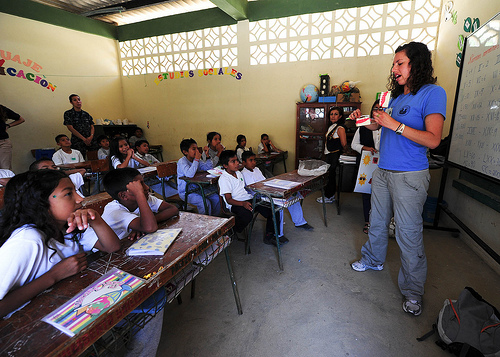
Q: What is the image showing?
A: It is showing a classroom.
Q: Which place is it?
A: It is a classroom.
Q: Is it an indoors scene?
A: Yes, it is indoors.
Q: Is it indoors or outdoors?
A: It is indoors.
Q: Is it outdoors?
A: No, it is indoors.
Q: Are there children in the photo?
A: Yes, there is a child.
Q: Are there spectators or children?
A: Yes, there is a child.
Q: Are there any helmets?
A: No, there are no helmets.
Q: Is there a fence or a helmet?
A: No, there are no helmets or fences.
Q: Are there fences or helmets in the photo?
A: No, there are no helmets or fences.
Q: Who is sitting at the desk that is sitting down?
A: The child is sitting at the desk.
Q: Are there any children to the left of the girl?
A: Yes, there is a child to the left of the girl.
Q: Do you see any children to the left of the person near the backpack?
A: Yes, there is a child to the left of the girl.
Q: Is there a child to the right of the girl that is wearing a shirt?
A: No, the child is to the left of the girl.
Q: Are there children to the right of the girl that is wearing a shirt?
A: No, the child is to the left of the girl.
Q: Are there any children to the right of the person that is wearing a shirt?
A: No, the child is to the left of the girl.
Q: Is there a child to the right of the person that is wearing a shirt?
A: No, the child is to the left of the girl.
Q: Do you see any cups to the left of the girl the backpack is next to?
A: No, there is a child to the left of the girl.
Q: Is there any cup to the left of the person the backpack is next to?
A: No, there is a child to the left of the girl.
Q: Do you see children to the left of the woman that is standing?
A: Yes, there is a child to the left of the woman.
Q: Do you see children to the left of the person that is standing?
A: Yes, there is a child to the left of the woman.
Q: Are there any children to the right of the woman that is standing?
A: No, the child is to the left of the woman.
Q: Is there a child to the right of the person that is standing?
A: No, the child is to the left of the woman.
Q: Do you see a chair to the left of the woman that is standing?
A: No, there is a child to the left of the woman.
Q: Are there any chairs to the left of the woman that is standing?
A: No, there is a child to the left of the woman.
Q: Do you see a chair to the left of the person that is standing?
A: No, there is a child to the left of the woman.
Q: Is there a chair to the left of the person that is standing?
A: No, there is a child to the left of the woman.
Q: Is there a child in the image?
A: Yes, there are children.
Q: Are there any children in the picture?
A: Yes, there are children.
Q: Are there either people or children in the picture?
A: Yes, there are children.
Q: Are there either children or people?
A: Yes, there are children.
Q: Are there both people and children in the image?
A: Yes, there are both children and a person.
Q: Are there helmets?
A: No, there are no helmets.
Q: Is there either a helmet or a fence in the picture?
A: No, there are no helmets or fences.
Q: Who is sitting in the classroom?
A: The kids are sitting in the classroom.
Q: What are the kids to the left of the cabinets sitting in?
A: The children are sitting in the classroom.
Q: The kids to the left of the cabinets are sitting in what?
A: The children are sitting in the classroom.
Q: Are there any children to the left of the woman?
A: Yes, there are children to the left of the woman.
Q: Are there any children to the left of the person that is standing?
A: Yes, there are children to the left of the woman.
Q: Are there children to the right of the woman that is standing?
A: No, the children are to the left of the woman.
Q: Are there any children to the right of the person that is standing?
A: No, the children are to the left of the woman.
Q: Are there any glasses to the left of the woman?
A: No, there are children to the left of the woman.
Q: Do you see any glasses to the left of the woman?
A: No, there are children to the left of the woman.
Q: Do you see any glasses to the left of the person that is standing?
A: No, there are children to the left of the woman.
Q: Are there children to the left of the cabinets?
A: Yes, there are children to the left of the cabinets.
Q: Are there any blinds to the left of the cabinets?
A: No, there are children to the left of the cabinets.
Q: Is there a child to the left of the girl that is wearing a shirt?
A: Yes, there are children to the left of the girl.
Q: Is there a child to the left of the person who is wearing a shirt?
A: Yes, there are children to the left of the girl.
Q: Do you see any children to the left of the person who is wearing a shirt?
A: Yes, there are children to the left of the girl.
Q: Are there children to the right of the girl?
A: No, the children are to the left of the girl.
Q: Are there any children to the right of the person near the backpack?
A: No, the children are to the left of the girl.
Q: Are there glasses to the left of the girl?
A: No, there are children to the left of the girl.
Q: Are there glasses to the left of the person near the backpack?
A: No, there are children to the left of the girl.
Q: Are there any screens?
A: No, there are no screens.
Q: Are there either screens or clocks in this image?
A: No, there are no screens or clocks.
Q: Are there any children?
A: Yes, there is a child.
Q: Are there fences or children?
A: Yes, there is a child.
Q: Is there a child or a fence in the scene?
A: Yes, there is a child.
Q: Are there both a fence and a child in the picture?
A: No, there is a child but no fences.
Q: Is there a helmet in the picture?
A: No, there are no helmets.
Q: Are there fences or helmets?
A: No, there are no helmets or fences.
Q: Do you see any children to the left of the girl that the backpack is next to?
A: Yes, there is a child to the left of the girl.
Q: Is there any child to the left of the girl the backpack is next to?
A: Yes, there is a child to the left of the girl.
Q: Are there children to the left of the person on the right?
A: Yes, there is a child to the left of the girl.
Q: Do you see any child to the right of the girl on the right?
A: No, the child is to the left of the girl.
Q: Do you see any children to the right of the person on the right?
A: No, the child is to the left of the girl.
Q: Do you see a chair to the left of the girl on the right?
A: No, there is a child to the left of the girl.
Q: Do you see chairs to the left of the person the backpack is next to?
A: No, there is a child to the left of the girl.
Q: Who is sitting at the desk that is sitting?
A: The child is sitting at the desk.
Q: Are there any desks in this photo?
A: Yes, there is a desk.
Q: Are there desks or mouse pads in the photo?
A: Yes, there is a desk.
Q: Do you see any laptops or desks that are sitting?
A: Yes, the desk is sitting.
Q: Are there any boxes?
A: No, there are no boxes.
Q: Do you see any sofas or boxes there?
A: No, there are no boxes or sofas.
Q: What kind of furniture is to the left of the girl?
A: The piece of furniture is a desk.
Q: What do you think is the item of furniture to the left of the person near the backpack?
A: The piece of furniture is a desk.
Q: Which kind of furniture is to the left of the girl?
A: The piece of furniture is a desk.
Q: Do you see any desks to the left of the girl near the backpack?
A: Yes, there is a desk to the left of the girl.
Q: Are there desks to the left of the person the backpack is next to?
A: Yes, there is a desk to the left of the girl.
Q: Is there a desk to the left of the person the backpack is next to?
A: Yes, there is a desk to the left of the girl.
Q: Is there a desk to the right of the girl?
A: No, the desk is to the left of the girl.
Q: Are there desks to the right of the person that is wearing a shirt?
A: No, the desk is to the left of the girl.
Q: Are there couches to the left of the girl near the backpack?
A: No, there is a desk to the left of the girl.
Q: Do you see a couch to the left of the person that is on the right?
A: No, there is a desk to the left of the girl.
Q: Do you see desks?
A: Yes, there is a desk.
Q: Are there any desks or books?
A: Yes, there is a desk.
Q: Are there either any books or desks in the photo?
A: Yes, there is a desk.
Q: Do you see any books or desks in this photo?
A: Yes, there is a desk.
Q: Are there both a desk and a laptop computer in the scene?
A: No, there is a desk but no laptops.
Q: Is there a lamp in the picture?
A: No, there are no lamps.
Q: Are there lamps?
A: No, there are no lamps.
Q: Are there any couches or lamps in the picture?
A: No, there are no lamps or couches.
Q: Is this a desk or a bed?
A: This is a desk.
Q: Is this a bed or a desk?
A: This is a desk.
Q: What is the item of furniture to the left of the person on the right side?
A: The piece of furniture is a desk.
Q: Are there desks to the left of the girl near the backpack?
A: Yes, there is a desk to the left of the girl.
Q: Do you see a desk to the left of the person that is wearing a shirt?
A: Yes, there is a desk to the left of the girl.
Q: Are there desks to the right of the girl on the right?
A: No, the desk is to the left of the girl.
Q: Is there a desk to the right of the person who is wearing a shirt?
A: No, the desk is to the left of the girl.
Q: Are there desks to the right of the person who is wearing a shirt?
A: No, the desk is to the left of the girl.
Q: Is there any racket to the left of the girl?
A: No, there is a desk to the left of the girl.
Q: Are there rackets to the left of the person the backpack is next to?
A: No, there is a desk to the left of the girl.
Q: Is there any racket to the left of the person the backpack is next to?
A: No, there is a desk to the left of the girl.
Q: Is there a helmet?
A: No, there are no helmets.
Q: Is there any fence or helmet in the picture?
A: No, there are no helmets or fences.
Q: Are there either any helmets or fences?
A: No, there are no helmets or fences.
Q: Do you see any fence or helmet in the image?
A: No, there are no helmets or fences.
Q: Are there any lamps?
A: No, there are no lamps.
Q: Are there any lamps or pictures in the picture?
A: No, there are no lamps or pictures.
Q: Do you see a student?
A: Yes, there is a student.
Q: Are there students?
A: Yes, there is a student.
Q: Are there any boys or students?
A: Yes, there is a student.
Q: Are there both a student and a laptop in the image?
A: No, there is a student but no laptops.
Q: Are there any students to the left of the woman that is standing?
A: Yes, there is a student to the left of the woman.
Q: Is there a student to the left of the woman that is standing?
A: Yes, there is a student to the left of the woman.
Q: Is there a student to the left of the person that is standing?
A: Yes, there is a student to the left of the woman.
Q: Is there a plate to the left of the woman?
A: No, there is a student to the left of the woman.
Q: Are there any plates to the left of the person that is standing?
A: No, there is a student to the left of the woman.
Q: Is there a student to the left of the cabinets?
A: Yes, there is a student to the left of the cabinets.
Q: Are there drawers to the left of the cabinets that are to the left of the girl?
A: No, there is a student to the left of the cabinets.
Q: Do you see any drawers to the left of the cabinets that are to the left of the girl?
A: No, there is a student to the left of the cabinets.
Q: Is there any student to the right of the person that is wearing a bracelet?
A: Yes, there is a student to the right of the person.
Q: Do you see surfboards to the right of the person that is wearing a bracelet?
A: No, there is a student to the right of the person.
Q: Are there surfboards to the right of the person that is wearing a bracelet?
A: No, there is a student to the right of the person.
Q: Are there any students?
A: Yes, there is a student.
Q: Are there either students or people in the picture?
A: Yes, there is a student.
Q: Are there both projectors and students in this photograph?
A: No, there is a student but no projectors.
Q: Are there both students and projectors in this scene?
A: No, there is a student but no projectors.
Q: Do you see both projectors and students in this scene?
A: No, there is a student but no projectors.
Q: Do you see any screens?
A: No, there are no screens.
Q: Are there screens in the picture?
A: No, there are no screens.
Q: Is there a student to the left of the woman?
A: Yes, there is a student to the left of the woman.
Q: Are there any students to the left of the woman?
A: Yes, there is a student to the left of the woman.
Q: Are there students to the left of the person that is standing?
A: Yes, there is a student to the left of the woman.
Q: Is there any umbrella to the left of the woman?
A: No, there is a student to the left of the woman.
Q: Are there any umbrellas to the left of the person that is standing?
A: No, there is a student to the left of the woman.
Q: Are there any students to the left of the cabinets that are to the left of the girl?
A: Yes, there is a student to the left of the cabinets.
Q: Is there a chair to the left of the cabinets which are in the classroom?
A: No, there is a student to the left of the cabinets.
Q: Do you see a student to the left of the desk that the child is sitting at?
A: Yes, there is a student to the left of the desk.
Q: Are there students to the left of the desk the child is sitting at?
A: Yes, there is a student to the left of the desk.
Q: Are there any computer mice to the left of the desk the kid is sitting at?
A: No, there is a student to the left of the desk.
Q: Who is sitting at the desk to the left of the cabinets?
A: The student is sitting at the desk.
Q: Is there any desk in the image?
A: Yes, there is a desk.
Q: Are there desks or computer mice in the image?
A: Yes, there is a desk.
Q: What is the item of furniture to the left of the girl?
A: The piece of furniture is a desk.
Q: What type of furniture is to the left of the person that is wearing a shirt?
A: The piece of furniture is a desk.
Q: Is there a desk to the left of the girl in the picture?
A: Yes, there is a desk to the left of the girl.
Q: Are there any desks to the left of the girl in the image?
A: Yes, there is a desk to the left of the girl.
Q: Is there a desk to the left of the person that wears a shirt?
A: Yes, there is a desk to the left of the girl.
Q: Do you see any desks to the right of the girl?
A: No, the desk is to the left of the girl.